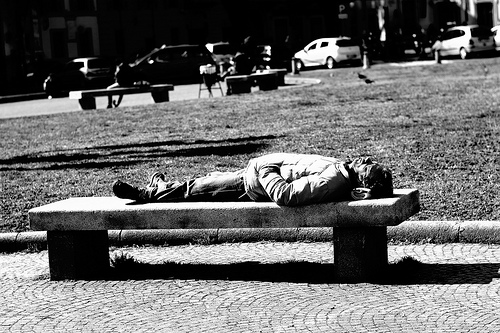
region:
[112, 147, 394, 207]
Man laying on the bench.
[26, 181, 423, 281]
Cement bench in the forefront.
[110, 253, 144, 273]
Weed growing under the bench.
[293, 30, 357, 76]
White car in the background.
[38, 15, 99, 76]
doors on a building.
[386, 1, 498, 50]
Home in the background.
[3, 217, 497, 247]
Cement curve in front of grass.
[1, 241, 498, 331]
Paving bricks covering the ground.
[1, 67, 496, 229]
Grass covering the ground.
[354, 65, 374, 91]
Birds in the grass.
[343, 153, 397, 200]
Head of recling person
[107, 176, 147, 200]
Foot of reclining person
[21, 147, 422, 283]
Bench with reclining person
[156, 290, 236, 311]
Brick pavement near person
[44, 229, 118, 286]
Support for stone bench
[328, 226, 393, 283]
Support for stone bench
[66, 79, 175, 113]
Stone bench in park area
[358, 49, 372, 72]
Traffic safety post for area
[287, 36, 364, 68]
Car parked near area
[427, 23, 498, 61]
Car parked near area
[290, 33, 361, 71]
car driving on road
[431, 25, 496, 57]
car driving on road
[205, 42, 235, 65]
car driving on road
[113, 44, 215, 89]
car driving on road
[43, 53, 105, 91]
car driving on road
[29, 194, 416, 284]
grey stone park bench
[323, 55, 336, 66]
round black care tire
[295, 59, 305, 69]
round black care tire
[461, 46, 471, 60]
round black care tire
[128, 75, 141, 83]
round black care tire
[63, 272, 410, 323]
concrete ground for walking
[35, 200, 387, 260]
bench for sitting made of stone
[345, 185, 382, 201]
rolled up cloth for resting head on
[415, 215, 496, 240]
curb to separate grass from walking area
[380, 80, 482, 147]
grassy areas well maintained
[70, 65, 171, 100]
bench with person sitting on it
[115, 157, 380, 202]
man laying on bench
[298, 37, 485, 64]
vehicles parked in the parking lot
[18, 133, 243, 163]
shadow of tree from above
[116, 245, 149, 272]
weeds growing through cracks in the concrete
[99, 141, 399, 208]
person laying down on a platform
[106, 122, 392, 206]
person wearing a jacket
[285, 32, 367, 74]
car parked on street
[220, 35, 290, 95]
people sitting down on bench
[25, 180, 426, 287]
a stone bench in the park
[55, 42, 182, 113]
person sitting down on bench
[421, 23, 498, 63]
car parked on street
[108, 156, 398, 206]
person wearing a pair of shoes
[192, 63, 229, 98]
garbage disposal bin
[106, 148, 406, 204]
person is wearing a jean